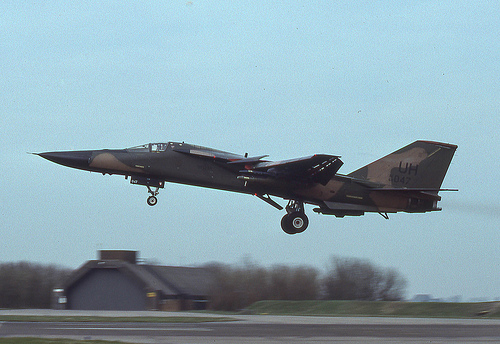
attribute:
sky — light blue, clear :
[12, 9, 496, 133]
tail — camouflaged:
[359, 144, 436, 186]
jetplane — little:
[22, 100, 449, 231]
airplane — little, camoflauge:
[24, 135, 463, 235]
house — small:
[55, 222, 221, 342]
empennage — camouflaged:
[346, 137, 459, 192]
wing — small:
[231, 150, 264, 168]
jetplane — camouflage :
[27, 138, 457, 234]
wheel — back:
[288, 210, 309, 233]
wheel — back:
[281, 211, 295, 233]